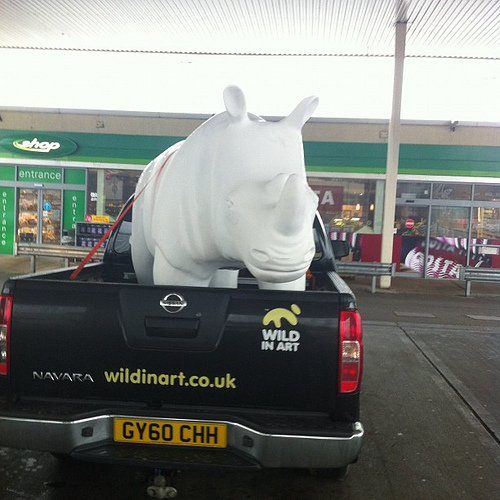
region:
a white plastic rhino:
[105, 79, 331, 309]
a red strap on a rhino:
[60, 133, 179, 282]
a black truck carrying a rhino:
[3, 190, 388, 468]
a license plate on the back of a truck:
[112, 411, 227, 454]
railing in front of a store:
[447, 261, 497, 286]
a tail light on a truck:
[330, 306, 365, 402]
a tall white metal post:
[367, 12, 413, 284]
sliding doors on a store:
[15, 180, 65, 247]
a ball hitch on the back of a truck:
[148, 470, 178, 495]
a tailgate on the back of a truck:
[0, 287, 347, 411]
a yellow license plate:
[111, 410, 229, 450]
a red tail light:
[335, 307, 362, 396]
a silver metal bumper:
[0, 410, 367, 470]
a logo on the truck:
[152, 291, 192, 317]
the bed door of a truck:
[0, 278, 358, 422]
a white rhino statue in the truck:
[117, 83, 346, 292]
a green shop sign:
[0, 130, 86, 160]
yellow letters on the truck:
[100, 360, 245, 400]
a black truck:
[0, 182, 369, 477]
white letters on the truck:
[256, 326, 302, 358]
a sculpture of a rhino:
[137, 108, 327, 288]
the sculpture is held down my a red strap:
[70, 86, 214, 296]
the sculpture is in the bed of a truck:
[130, 105, 330, 360]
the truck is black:
[55, 291, 365, 446]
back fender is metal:
[16, 395, 363, 462]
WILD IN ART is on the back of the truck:
[260, 319, 320, 354]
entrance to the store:
[16, 160, 91, 249]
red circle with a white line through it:
[398, 214, 422, 237]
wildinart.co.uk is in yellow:
[104, 353, 261, 398]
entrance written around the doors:
[3, 164, 124, 261]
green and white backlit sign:
[2, 131, 76, 158]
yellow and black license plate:
[113, 413, 228, 451]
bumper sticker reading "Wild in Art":
[253, 299, 304, 354]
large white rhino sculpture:
[122, 82, 324, 292]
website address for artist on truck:
[104, 365, 237, 392]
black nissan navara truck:
[2, 185, 364, 479]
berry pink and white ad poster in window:
[397, 230, 495, 281]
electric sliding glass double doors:
[13, 180, 63, 250]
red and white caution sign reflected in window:
[404, 216, 415, 227]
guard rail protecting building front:
[455, 266, 499, 296]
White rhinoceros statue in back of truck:
[111, 99, 336, 294]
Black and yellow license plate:
[113, 417, 230, 452]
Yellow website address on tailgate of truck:
[100, 362, 247, 398]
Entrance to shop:
[1, 156, 79, 259]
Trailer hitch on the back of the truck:
[144, 465, 181, 498]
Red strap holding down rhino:
[61, 173, 163, 282]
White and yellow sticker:
[256, 301, 308, 356]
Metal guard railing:
[347, 259, 402, 291]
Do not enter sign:
[402, 216, 418, 230]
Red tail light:
[334, 306, 364, 403]